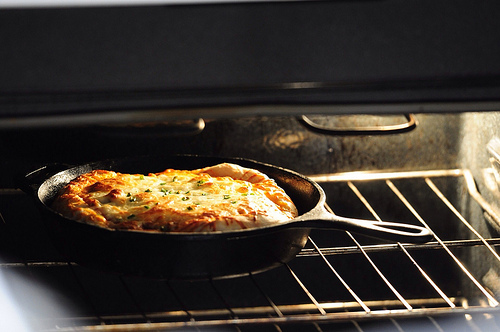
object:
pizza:
[61, 162, 297, 232]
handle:
[292, 208, 433, 244]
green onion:
[223, 194, 230, 199]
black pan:
[21, 154, 434, 282]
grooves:
[479, 138, 500, 282]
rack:
[0, 167, 500, 332]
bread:
[55, 162, 299, 232]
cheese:
[57, 163, 297, 233]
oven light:
[305, 111, 496, 170]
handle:
[306, 206, 432, 241]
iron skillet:
[21, 152, 433, 283]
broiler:
[294, 113, 427, 147]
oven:
[0, 0, 500, 332]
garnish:
[115, 175, 215, 227]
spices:
[105, 169, 239, 219]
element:
[295, 113, 420, 133]